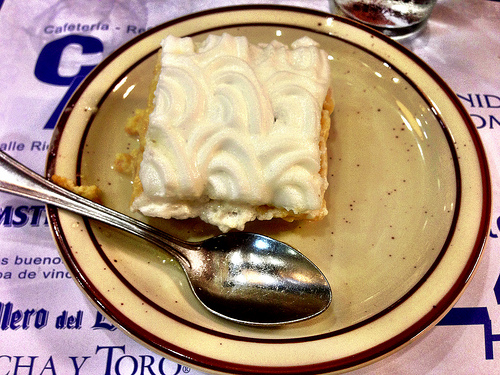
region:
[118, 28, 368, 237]
Delicious piece of pie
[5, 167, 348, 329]
Clean silver spoon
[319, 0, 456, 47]
Glass of water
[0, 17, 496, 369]
Delicious dessert dish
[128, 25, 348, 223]
Fluffy white decorative frosting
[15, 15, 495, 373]
Tan plate with brown trim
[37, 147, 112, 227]
Piece of pie stuck under the spoon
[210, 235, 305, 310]
Light reflecting from the spoon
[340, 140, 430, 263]
Dark specks in the plates design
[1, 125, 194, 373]
Writing on the table mat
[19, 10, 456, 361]
A desert platter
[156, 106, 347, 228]
A lemon marange pie square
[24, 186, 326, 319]
A metal spoon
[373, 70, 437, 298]
A brown plate the dessert is sitting on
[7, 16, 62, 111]
A table decorated with words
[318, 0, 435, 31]
A metal ustensil next to the plate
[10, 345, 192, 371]
Blue words "Chay Toro" on the table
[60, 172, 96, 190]
Crumb of lemon marange pie seperated from square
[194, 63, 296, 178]
Marange on top of the pie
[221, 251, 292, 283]
Lights relfected in the spoon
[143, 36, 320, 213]
decorative white frosting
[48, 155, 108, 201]
cake crumb on plate edge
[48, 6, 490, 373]
beige speckled plate with dark brown rim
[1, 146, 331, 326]
stainless steel spoon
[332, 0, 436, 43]
base of drinking glass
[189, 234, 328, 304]
ceiling lights reflected in a spoon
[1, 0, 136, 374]
a place mat with blue print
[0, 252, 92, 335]
words in spanish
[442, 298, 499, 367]
blue right angles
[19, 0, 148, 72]
a water ring left by a wet glass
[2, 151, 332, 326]
old silver teaspoon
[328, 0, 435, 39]
bottom of a glass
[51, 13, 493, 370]
old yellow plate with brown trim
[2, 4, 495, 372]
purple cafeteria placemat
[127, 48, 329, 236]
piece of cake with white frosting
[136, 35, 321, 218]
white frosting with a wave design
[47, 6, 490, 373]
small plate with a piece of cake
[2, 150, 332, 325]
tarnished old spoon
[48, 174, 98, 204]
cake crumbs near the spoon's handle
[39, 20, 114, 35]
The word cafeteria on the placemat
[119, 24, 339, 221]
Pastry sitting on a plate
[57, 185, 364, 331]
Spoon laying on the plate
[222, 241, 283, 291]
Light reflection in the spoon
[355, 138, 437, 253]
The plate is speckled design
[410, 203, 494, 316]
The plate has stripes on it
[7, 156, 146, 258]
Handle on the spoon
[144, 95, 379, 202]
White icing on the pastry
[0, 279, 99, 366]
Table cloth has writing on it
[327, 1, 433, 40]
Glass sitting on the table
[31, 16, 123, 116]
Wording on the paper